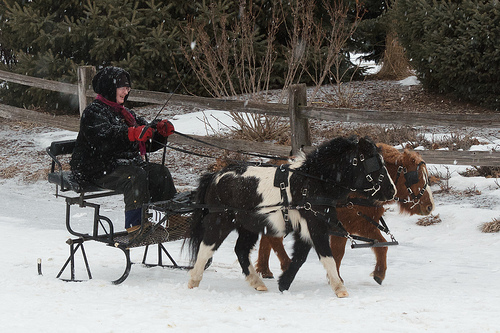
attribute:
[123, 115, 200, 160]
gloves — red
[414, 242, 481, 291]
snow — white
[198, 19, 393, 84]
tree — brown, green, dead, winter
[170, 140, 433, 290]
horses — walking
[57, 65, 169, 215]
coat — black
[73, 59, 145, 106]
hat — black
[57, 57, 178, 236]
woman — white, riding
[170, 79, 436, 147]
fence — wooden, brown, background, worn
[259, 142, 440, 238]
horse — red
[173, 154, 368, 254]
horse — black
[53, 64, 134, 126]
face — old woman's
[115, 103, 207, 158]
mittens — red winter , red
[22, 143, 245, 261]
sleigh — old woman's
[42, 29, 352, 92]
branch — brown , background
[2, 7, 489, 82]
trees — green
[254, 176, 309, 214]
spot — white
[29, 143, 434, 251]
horses — pulling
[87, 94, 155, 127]
scarf — red, cranberry-colored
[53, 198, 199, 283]
sled — metal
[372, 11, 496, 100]
fern — green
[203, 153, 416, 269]
pony — black, white, miniature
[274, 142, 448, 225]
pony — red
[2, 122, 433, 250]
ponies — pulling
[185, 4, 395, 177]
scrubs — brown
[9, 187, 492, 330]
road — covered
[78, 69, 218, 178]
person — holding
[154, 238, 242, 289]
leg — white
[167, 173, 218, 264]
tail — black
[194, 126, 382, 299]
horse — black 